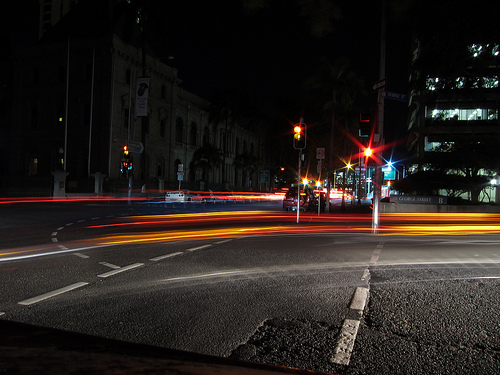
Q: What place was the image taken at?
A: It was taken at the road.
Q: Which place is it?
A: It is a road.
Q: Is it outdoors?
A: Yes, it is outdoors.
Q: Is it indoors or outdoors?
A: It is outdoors.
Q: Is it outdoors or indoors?
A: It is outdoors.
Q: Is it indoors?
A: No, it is outdoors.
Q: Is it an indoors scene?
A: No, it is outdoors.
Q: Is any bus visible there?
A: No, there are no buses.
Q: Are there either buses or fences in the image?
A: No, there are no buses or fences.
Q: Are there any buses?
A: No, there are no buses.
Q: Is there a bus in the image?
A: No, there are no buses.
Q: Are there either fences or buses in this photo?
A: No, there are no buses or fences.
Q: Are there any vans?
A: No, there are no vans.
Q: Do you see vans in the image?
A: No, there are no vans.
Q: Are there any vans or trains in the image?
A: No, there are no vans or trains.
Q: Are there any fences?
A: No, there are no fences.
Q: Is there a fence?
A: No, there are no fences.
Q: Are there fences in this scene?
A: No, there are no fences.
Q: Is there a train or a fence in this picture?
A: No, there are no fences or trains.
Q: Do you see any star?
A: Yes, there is a star.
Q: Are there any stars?
A: Yes, there is a star.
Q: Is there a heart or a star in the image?
A: Yes, there is a star.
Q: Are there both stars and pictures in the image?
A: No, there is a star but no pictures.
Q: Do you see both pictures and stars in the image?
A: No, there is a star but no pictures.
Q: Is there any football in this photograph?
A: No, there are no footballs.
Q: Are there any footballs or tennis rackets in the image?
A: No, there are no footballs or tennis rackets.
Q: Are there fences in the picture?
A: No, there are no fences.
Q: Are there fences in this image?
A: No, there are no fences.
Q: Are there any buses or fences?
A: No, there are no fences or buses.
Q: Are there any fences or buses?
A: No, there are no fences or buses.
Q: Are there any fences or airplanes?
A: No, there are no fences or airplanes.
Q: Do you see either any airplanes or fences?
A: No, there are no fences or airplanes.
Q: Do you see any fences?
A: No, there are no fences.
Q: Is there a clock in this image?
A: No, there are no clocks.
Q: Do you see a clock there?
A: No, there are no clocks.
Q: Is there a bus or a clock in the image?
A: No, there are no clocks or buses.